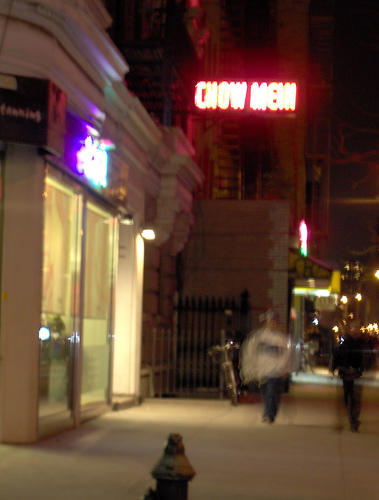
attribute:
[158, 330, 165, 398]
pole — metal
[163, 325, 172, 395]
pole — metal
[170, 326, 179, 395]
pole — metal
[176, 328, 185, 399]
pole — metal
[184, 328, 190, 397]
pole — metal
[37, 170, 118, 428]
windows — tall, grass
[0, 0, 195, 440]
business — commercial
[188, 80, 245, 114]
word — flowing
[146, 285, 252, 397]
fence — tall, metal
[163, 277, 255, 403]
black fence — tall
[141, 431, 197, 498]
hydrant — fire, in foreground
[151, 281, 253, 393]
fence — tall, black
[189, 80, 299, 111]
chow mein — on sign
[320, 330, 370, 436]
person — in black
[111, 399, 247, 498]
fire hydrant — top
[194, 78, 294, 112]
sign — neon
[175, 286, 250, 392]
fence — black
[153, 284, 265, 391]
fence — black, tall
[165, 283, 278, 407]
fence — tall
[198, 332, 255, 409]
bike — parked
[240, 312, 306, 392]
shirt — white